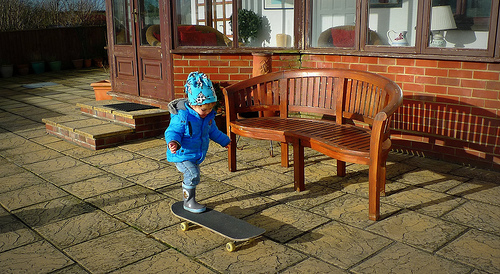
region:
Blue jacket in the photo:
[166, 109, 221, 158]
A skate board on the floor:
[167, 190, 264, 260]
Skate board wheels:
[170, 219, 248, 261]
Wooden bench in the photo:
[218, 64, 387, 156]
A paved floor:
[53, 152, 130, 239]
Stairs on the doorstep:
[41, 77, 155, 159]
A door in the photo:
[112, 0, 170, 95]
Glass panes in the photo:
[197, 1, 419, 47]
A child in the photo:
[157, 69, 232, 211]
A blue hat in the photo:
[183, 73, 217, 106]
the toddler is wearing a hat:
[183, 75, 218, 107]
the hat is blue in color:
[185, 73, 215, 108]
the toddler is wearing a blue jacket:
[166, 100, 222, 165]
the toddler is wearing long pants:
[174, 155, 201, 191]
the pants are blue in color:
[169, 158, 209, 185]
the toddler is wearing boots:
[181, 183, 200, 213]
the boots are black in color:
[179, 183, 204, 213]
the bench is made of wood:
[223, 63, 403, 219]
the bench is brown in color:
[221, 68, 401, 224]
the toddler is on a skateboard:
[162, 73, 259, 247]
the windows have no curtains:
[371, 9, 415, 42]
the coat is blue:
[179, 118, 201, 147]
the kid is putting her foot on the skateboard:
[176, 127, 216, 255]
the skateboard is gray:
[217, 213, 250, 243]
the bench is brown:
[291, 116, 334, 151]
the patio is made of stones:
[69, 186, 136, 255]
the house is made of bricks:
[422, 71, 469, 122]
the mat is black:
[111, 95, 145, 123]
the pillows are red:
[185, 31, 200, 40]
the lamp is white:
[430, 6, 455, 39]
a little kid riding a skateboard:
[159, 67, 234, 217]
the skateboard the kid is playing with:
[166, 198, 264, 253]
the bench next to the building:
[222, 64, 402, 216]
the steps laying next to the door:
[40, 90, 159, 166]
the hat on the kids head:
[185, 68, 220, 108]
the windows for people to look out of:
[181, 3, 498, 54]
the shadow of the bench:
[373, 88, 497, 230]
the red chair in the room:
[318, 23, 375, 46]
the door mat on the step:
[101, 94, 156, 118]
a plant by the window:
[235, 8, 278, 53]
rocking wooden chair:
[222, 79, 404, 213]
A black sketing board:
[171, 200, 262, 241]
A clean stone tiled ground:
[42, 193, 151, 271]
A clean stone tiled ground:
[303, 214, 339, 272]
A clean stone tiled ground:
[418, 205, 486, 270]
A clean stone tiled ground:
[17, 140, 93, 176]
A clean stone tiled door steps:
[50, 100, 160, 175]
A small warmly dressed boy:
[167, 66, 227, 201]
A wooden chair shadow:
[420, 90, 495, 180]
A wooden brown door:
[106, 52, 169, 93]